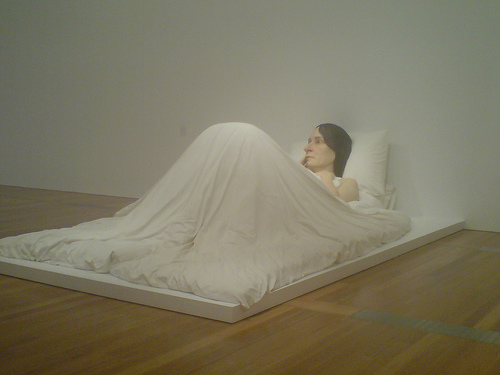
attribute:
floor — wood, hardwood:
[0, 180, 497, 372]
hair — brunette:
[315, 123, 353, 178]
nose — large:
[302, 144, 314, 153]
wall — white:
[2, 0, 498, 234]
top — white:
[317, 173, 343, 186]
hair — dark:
[318, 120, 351, 178]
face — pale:
[302, 124, 336, 167]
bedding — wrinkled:
[2, 120, 411, 309]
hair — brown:
[317, 120, 354, 179]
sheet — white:
[9, 120, 413, 309]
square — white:
[0, 215, 468, 325]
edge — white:
[0, 256, 236, 324]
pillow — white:
[290, 124, 392, 213]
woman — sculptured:
[295, 121, 363, 206]